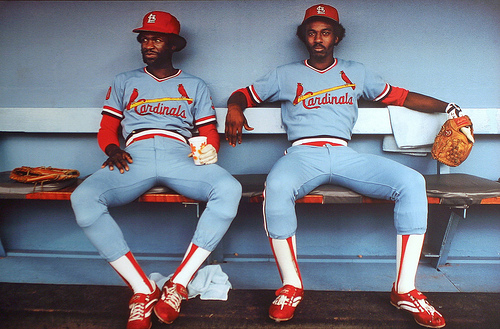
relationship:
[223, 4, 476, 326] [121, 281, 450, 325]
ball player wearing shoes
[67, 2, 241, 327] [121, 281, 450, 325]
ball player wearing shoes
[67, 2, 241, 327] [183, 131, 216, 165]
ball player holding cup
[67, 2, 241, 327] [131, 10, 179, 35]
ball player wearing hat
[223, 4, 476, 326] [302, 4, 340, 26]
ball player wearing hat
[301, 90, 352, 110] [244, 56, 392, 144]
cardinals on jersey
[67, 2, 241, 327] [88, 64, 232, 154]
ball player wearing jersey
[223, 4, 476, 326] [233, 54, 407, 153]
ball player wearing jersey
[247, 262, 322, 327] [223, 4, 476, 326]
foot on ball player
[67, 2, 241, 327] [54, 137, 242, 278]
ball player wearing pants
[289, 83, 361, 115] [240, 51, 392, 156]
logo on jersey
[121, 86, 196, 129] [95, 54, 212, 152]
logo on jersey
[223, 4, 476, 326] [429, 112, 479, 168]
ball player holding mitt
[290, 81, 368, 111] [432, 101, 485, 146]
letters on glove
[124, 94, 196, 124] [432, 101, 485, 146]
letters on glove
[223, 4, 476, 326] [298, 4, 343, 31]
ball player wearing hat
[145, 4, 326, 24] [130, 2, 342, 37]
white letter on hats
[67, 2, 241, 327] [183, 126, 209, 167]
ball player holding cup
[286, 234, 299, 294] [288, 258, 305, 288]
part of line